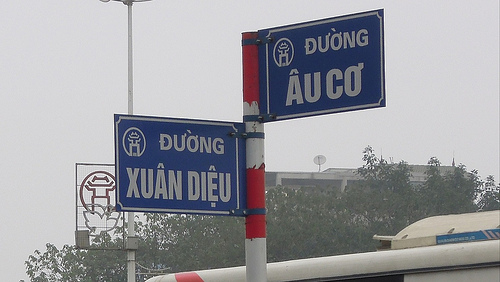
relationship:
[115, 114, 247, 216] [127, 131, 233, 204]
sign has writing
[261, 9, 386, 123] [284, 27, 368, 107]
sign has writing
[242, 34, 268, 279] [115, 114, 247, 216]
pole has sign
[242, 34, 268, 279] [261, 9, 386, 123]
pole has sign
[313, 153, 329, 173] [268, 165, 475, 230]
dish on top of building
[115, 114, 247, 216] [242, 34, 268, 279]
sign attached to pole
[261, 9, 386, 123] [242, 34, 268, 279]
sign attached to pole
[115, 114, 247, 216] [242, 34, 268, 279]
sign hanging on pole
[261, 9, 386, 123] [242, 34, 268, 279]
sign hanging on pole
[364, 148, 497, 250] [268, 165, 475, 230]
tree next to building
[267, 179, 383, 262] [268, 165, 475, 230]
tree next to building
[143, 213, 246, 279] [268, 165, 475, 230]
tree next to building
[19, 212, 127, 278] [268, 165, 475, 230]
tree next to building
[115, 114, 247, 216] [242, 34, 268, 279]
sign hanging from pole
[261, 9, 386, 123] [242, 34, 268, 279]
sign hanging from pole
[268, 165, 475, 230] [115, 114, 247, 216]
building has sign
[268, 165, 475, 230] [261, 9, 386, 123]
building has sign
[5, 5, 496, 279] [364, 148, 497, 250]
skies are above tree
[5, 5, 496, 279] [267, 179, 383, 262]
skies are above tree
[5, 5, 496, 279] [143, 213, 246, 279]
skies are above tree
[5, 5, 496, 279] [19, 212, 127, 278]
skies are above tree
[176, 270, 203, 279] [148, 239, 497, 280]
mark on top of pipe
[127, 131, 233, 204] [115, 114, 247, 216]
writing on top of sign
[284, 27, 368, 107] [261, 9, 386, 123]
writing on top of sign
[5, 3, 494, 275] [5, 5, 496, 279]
view has skies